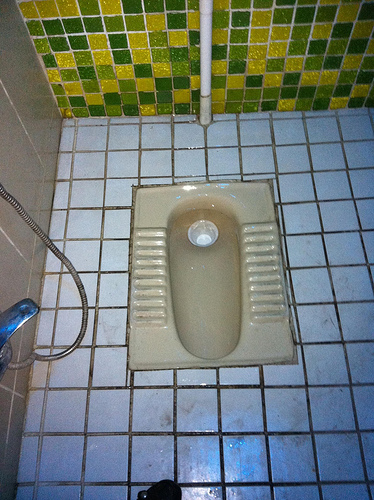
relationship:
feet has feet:
[242, 227, 282, 322] [242, 221, 287, 324]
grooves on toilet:
[234, 216, 293, 317] [132, 179, 292, 360]